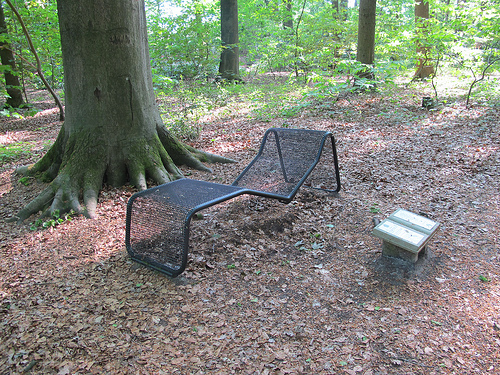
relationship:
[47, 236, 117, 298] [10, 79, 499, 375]
leaves on ground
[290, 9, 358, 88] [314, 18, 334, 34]
tree has leaves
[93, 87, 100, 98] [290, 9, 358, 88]
notch in tree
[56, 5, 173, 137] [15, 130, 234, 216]
tree trunk has tree roots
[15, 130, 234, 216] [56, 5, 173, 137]
tree roots of tree trunk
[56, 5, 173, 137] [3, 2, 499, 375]
tree trunk in forest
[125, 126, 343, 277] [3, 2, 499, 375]
bench in forest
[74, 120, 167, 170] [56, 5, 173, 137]
moss growing on tree trunk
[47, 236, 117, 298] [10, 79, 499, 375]
leaves covering ground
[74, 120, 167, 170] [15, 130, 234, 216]
moss growing on tree roots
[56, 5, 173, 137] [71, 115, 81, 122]
tree trunk has hole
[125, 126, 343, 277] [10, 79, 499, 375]
bench on top of ground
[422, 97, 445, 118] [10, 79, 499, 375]
sign on top of ground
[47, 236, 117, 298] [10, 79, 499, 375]
leaves on top of ground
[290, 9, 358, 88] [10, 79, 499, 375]
tree on top of ground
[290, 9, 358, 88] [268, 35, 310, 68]
tree has branches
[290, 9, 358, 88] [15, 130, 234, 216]
tree has tree roots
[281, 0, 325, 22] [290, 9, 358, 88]
sky in between tree